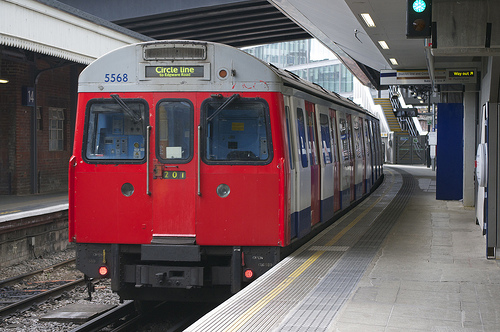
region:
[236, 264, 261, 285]
red lights on train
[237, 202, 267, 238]
the train is red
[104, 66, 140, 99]
four numbers on vehicle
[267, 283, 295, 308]
yellow lines on ground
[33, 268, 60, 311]
tracks for the train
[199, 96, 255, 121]
wipers on the train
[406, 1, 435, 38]
green light on roof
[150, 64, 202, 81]
words on the train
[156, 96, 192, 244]
a door to exit train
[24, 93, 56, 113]
number on the wall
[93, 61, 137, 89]
number on outside on train car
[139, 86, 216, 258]
entrance door on train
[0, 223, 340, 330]
train tracks with gravel in between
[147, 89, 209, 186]
window in back door of train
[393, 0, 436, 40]
traffic light in train station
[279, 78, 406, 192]
side windows on train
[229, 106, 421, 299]
yellow line painted in train terminal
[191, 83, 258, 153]
windshield wipers on outside of train car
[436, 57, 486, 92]
digita sign in train station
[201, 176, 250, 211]
head lights on front of train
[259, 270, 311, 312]
yellow line painted on train platform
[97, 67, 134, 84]
blue numbers on front of train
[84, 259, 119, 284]
small red light on front of train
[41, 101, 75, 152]
window on side of building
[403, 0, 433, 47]
small traffic signal indicating green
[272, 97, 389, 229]
windows on side of train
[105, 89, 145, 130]
black metal wind shield wiper on train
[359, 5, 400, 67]
lights on ceiling of train platform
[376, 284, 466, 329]
grey stone tile on train platform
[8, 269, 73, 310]
brown metal train tracks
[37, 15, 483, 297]
empty train station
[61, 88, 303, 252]
front of the train is red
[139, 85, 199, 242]
red door on the front of the train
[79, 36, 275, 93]
very top of the train is grey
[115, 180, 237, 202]
two headlights on the front of the train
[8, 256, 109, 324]
gravel is between the tracks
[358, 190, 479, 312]
walkway leading to the train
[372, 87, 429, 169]
stairs to get to street level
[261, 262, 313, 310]
yellow caution line on platform floor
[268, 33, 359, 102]
parts of buildings in the background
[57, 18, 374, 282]
this is a train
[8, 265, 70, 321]
this is a railway line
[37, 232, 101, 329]
this is a railway line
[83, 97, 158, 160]
a window on a train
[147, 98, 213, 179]
a window on a train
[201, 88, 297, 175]
a window on a train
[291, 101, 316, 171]
a window on a train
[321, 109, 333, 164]
a window on a train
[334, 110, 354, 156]
a window on a train